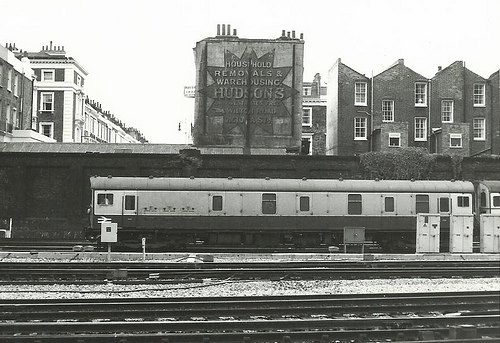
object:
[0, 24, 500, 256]
background buildings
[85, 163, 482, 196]
tone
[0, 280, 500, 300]
gravel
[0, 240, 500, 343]
ground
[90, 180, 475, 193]
roof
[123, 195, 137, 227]
door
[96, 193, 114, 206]
window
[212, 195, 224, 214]
window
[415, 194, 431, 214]
window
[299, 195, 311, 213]
window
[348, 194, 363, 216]
window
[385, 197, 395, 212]
window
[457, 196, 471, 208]
windows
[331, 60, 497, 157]
building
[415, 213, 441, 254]
power box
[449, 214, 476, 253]
power box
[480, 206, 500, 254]
power box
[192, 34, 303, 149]
advertisement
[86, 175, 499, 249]
train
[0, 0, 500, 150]
white sky